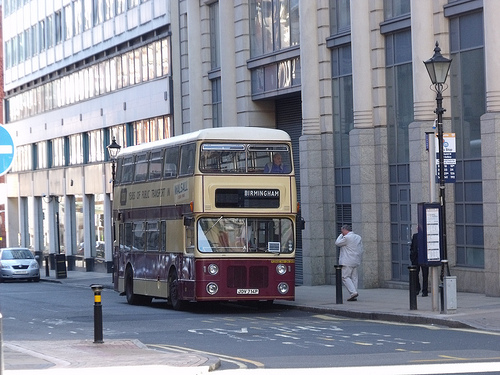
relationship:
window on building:
[251, 55, 302, 97] [3, 0, 174, 271]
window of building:
[234, 55, 321, 92] [166, 0, 498, 298]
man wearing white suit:
[329, 221, 369, 308] [337, 235, 364, 295]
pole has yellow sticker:
[90, 282, 103, 342] [94, 294, 101, 303]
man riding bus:
[332, 223, 365, 302] [110, 122, 300, 302]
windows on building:
[26, 197, 111, 256] [3, 0, 117, 277]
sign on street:
[2, 121, 23, 183] [34, 277, 444, 367]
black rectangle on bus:
[215, 188, 282, 211] [110, 122, 300, 302]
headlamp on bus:
[275, 261, 287, 276] [110, 122, 300, 302]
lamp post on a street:
[418, 40, 458, 311] [99, 307, 346, 355]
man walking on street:
[332, 223, 365, 302] [294, 296, 424, 346]